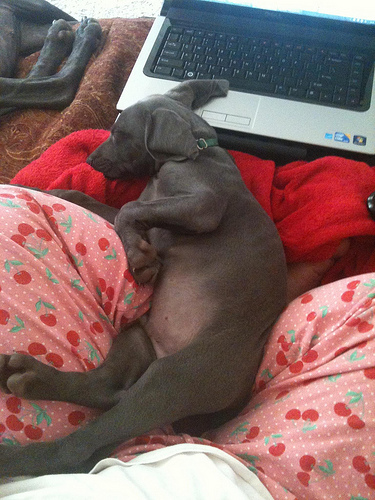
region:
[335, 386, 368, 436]
cherry graphic on white on pink polka dotted fabric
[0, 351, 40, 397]
exposed foot pad of dog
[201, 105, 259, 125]
touchpad mouse buttons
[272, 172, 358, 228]
red crumpled towel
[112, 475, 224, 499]
white sheet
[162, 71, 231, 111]
floppy dog ear on laptop keyboard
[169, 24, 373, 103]
normal sized laptop keyboard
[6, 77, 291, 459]
sleeping brown puppy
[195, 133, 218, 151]
verdant green colar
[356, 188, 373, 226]
black wireless mouse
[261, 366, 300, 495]
the pillow is pink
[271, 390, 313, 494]
the pillow is pink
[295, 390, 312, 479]
the pillow is pink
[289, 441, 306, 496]
the pillow is pink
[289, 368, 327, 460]
the pillow is pink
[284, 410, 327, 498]
the pillow is pink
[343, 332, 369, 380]
the pillow is pink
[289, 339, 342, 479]
the pillow is pink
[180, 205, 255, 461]
the dog is asleep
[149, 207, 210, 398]
the dog is asleep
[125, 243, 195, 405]
the dog is asleep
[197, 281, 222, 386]
the dog is asleep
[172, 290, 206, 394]
the dog is asleep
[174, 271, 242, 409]
the dog is asleep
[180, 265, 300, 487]
the dog is asleep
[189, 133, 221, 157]
A blue collar around the puppy's neck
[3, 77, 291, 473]
A puppy is sleeping in the woman's lap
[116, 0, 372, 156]
A laptop is behind the puppy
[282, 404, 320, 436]
Cherries on the woman's pants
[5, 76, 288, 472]
Dog with short fur is asleep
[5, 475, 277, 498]
Woman is wearing a white shirt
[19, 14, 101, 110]
A dog's feet are visible by the laptop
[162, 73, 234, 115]
Dog's ear rests on laptop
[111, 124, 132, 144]
Puppy's eyes are closed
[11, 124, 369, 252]
A red cloth is under the dog's head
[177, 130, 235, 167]
dark green dog collar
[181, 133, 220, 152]
dark green dog collar